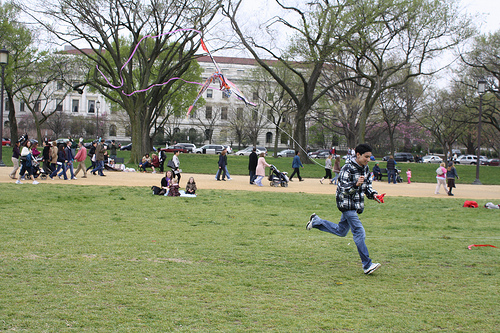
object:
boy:
[302, 143, 391, 275]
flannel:
[333, 153, 378, 213]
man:
[214, 147, 230, 182]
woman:
[251, 151, 269, 188]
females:
[442, 161, 461, 196]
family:
[148, 170, 200, 198]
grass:
[0, 180, 499, 333]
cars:
[190, 144, 233, 157]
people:
[69, 135, 87, 180]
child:
[405, 167, 415, 184]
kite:
[89, 28, 258, 111]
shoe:
[303, 211, 321, 231]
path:
[0, 166, 499, 201]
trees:
[7, 0, 252, 165]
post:
[471, 98, 485, 186]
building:
[0, 44, 364, 149]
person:
[90, 138, 108, 178]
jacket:
[72, 146, 90, 163]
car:
[159, 143, 197, 153]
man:
[288, 148, 304, 182]